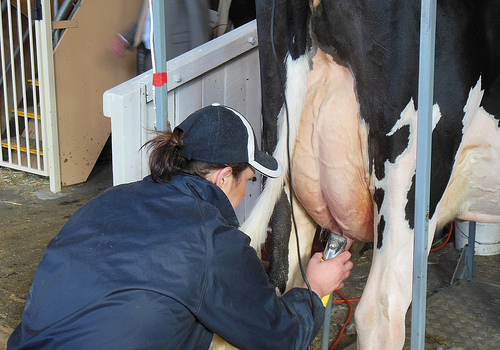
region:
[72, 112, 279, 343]
this is a lady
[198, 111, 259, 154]
this is a cap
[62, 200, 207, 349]
this is a jacket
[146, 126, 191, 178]
this is the hair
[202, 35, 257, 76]
this is a door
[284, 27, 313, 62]
this is the tail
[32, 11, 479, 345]
lady milking a cow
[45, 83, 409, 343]
lady in a blue coat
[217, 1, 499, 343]
rear end of a cow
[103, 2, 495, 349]
cow in a stall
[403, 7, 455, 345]
blue metal pole in a barn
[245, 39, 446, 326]
milking cow's teets being milked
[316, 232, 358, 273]
silver electronic device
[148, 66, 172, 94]
red tape on a pole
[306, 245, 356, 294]
a woman's hand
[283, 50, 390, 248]
a tan vein covered cow utter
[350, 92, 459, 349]
black and white spotted cow leg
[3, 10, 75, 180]
small staircase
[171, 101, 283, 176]
white and blue baseball hat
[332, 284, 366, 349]
red cord on the ground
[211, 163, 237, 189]
a woman's ear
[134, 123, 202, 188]
brown hair in a ponytail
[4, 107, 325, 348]
a woman milking a cow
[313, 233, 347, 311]
a milking hose in a woman's hand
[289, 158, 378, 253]
the full udder of a cow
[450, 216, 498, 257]
a white bucket behind a cow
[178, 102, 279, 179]
a black and white cap on a woman's head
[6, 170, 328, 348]
a black jacket on a woman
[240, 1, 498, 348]
a black and white cow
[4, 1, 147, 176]
a metal staircase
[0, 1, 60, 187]
a white gate on a metal staircase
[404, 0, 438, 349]
a metal post next to a cow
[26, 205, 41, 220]
this is the floor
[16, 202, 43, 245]
the floor is grey in color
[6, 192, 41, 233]
the floor is clean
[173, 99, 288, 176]
this is a cap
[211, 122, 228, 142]
the cap is black in color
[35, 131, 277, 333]
this is a woman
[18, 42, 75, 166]
these are some stairs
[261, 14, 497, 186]
this is a cow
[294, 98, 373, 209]
these are the cow's mammary glands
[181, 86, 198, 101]
the area is white in color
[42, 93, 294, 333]
A woman with a blue jacket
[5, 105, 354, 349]
Woman with blue hat and jacket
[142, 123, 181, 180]
Pony tail of woman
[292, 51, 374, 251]
Udder on black and white cow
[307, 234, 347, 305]
Milking machine attached to udder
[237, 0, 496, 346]
Black and white cow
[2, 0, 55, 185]
Metal gate in front of stairs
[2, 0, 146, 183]
Stairs next to cow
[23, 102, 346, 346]
Woman holding a milking device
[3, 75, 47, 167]
Yellow stripe on front of stairs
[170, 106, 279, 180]
blue and white hat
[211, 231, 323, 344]
arm of a woman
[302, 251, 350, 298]
hand of a woman